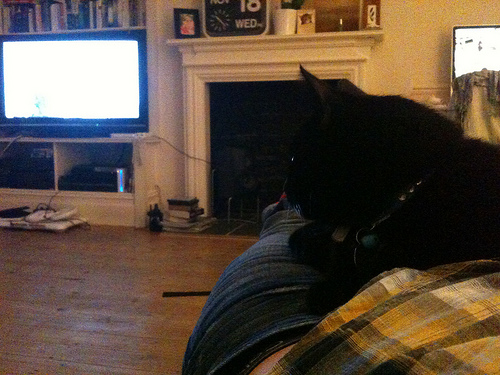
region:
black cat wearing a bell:
[300, 67, 496, 255]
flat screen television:
[0, 38, 150, 134]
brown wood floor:
[10, 235, 160, 370]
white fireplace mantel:
[171, 35, 386, 62]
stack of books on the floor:
[164, 195, 209, 234]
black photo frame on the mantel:
[174, 8, 201, 39]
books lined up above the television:
[4, 2, 154, 30]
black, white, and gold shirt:
[386, 278, 493, 369]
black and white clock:
[208, 8, 231, 35]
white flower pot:
[270, 7, 297, 37]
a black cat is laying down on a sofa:
[266, 66, 496, 281]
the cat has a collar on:
[290, 72, 460, 268]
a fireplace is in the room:
[190, 70, 360, 235]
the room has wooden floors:
[3, 206, 263, 369]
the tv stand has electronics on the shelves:
[3, 133, 153, 225]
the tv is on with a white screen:
[0, 31, 151, 138]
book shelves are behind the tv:
[1, 0, 141, 30]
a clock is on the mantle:
[200, 5, 262, 37]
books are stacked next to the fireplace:
[157, 190, 207, 232]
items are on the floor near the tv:
[1, 197, 88, 236]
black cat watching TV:
[282, 61, 493, 241]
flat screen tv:
[1, 38, 153, 130]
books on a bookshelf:
[5, 5, 146, 26]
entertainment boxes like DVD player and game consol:
[0, 145, 144, 232]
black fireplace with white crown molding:
[174, 37, 374, 232]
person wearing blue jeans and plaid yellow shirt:
[184, 200, 485, 364]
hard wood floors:
[8, 247, 252, 364]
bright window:
[444, 22, 498, 94]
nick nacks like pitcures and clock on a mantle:
[168, 0, 396, 31]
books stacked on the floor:
[160, 188, 234, 245]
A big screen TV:
[9, 40, 145, 122]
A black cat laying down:
[290, 90, 488, 261]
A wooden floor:
[36, 275, 154, 365]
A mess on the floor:
[18, 202, 83, 238]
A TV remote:
[154, 277, 218, 303]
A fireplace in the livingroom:
[207, 64, 294, 239]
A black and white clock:
[197, 3, 282, 43]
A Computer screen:
[453, 26, 499, 87]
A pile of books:
[153, 187, 221, 247]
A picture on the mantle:
[171, 13, 211, 63]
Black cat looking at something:
[256, 77, 491, 266]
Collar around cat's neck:
[340, 141, 457, 273]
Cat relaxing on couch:
[251, 71, 498, 257]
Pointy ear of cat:
[297, 63, 370, 124]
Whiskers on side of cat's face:
[263, 187, 315, 239]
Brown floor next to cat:
[29, 235, 181, 353]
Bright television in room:
[0, 25, 159, 142]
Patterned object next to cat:
[364, 266, 491, 370]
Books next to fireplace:
[163, 182, 225, 247]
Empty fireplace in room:
[169, 57, 289, 233]